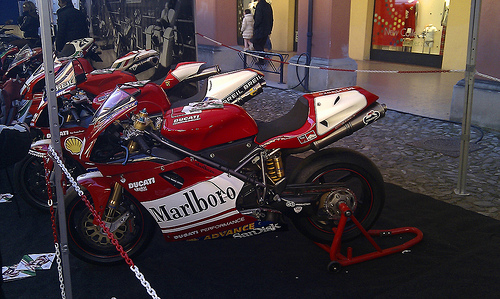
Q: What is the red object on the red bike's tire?
A: Stand.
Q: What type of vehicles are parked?
A: Motorcycles.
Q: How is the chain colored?
A: Red & white.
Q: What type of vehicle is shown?
A: Motorcycles.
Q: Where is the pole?
A: In front of the motorcycles.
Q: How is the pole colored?
A: Gray.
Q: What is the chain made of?
A: Metal.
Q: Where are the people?
A: Behind the motorcycles.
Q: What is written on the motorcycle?
A: Marlboro.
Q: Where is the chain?
A: In front of & behind the motorcycles.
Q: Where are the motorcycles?
A: On carpet.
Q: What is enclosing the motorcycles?
A: Red and white chain.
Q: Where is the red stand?
A: Back tires.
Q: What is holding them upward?
A: That rear wheel holder.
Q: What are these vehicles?
A: Sport bikes.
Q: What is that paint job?
A: A banner from a major sponser.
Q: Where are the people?
A: Way behind the rear of these bikes.